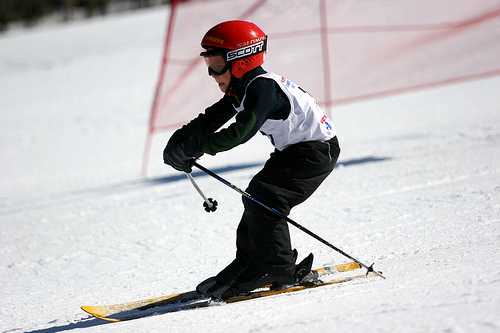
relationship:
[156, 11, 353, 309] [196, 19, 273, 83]
boy has helmet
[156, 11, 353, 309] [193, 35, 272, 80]
boy has goggles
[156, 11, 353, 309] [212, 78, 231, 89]
boy has mouth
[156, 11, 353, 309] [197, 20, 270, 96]
boy has head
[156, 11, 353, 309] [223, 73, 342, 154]
boy wearing jersey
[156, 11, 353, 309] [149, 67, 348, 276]
boy wearing suit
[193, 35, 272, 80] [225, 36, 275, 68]
goggles have strap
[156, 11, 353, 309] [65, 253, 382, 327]
boy has skis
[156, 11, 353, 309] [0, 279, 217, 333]
boy has shadow